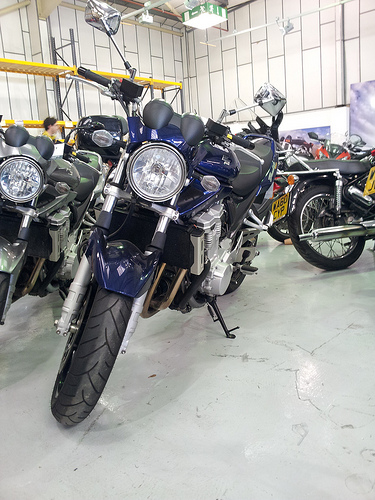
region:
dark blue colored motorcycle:
[96, 228, 146, 300]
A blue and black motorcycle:
[20, 53, 314, 419]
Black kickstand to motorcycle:
[188, 287, 248, 361]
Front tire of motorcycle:
[40, 268, 164, 443]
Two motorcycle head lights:
[6, 147, 199, 234]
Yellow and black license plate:
[264, 194, 298, 225]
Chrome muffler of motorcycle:
[294, 216, 374, 254]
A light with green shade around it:
[179, 1, 230, 40]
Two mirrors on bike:
[76, 7, 301, 146]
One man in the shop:
[30, 110, 85, 164]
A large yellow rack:
[1, 48, 191, 174]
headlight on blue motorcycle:
[127, 141, 192, 204]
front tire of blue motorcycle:
[46, 265, 145, 428]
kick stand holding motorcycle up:
[201, 293, 240, 343]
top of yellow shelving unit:
[3, 52, 187, 99]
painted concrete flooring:
[144, 342, 360, 461]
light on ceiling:
[177, 1, 234, 30]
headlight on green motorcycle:
[1, 156, 46, 203]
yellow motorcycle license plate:
[267, 190, 290, 221]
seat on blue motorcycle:
[226, 136, 275, 189]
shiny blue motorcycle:
[41, 58, 286, 406]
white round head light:
[127, 140, 189, 211]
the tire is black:
[87, 222, 216, 341]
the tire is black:
[34, 288, 141, 436]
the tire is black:
[43, 256, 187, 491]